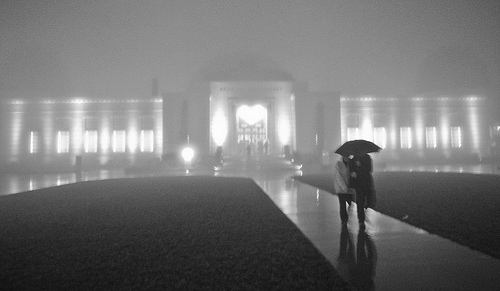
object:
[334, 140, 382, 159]
umbrella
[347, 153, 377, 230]
people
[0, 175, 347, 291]
grass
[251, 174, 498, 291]
sidewalk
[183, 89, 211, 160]
pillars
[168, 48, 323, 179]
front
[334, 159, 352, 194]
coat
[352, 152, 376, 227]
clothes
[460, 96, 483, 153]
lights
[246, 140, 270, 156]
people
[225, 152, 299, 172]
door step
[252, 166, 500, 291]
pavement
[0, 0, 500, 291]
picture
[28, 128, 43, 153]
window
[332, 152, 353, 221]
couple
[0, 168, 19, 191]
reflection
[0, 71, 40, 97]
dome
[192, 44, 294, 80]
dome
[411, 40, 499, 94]
dome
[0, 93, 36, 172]
building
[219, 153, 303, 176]
stairs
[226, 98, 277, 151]
entrance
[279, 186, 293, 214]
refelction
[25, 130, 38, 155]
windows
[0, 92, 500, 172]
wall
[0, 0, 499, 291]
scene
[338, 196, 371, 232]
walking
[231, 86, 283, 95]
words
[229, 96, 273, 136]
window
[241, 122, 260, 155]
door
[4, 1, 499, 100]
sky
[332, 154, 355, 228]
man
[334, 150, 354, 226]
woman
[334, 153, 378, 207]
jackets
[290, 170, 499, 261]
grass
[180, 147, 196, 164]
light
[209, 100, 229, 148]
light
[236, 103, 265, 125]
light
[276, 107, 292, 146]
light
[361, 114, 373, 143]
light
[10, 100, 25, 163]
light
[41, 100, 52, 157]
light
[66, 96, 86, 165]
light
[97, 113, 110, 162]
light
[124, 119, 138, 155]
light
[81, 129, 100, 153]
window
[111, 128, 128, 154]
window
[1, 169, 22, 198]
light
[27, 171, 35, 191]
light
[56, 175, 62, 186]
light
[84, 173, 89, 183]
light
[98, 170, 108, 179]
light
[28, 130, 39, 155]
window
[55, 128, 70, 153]
window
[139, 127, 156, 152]
window